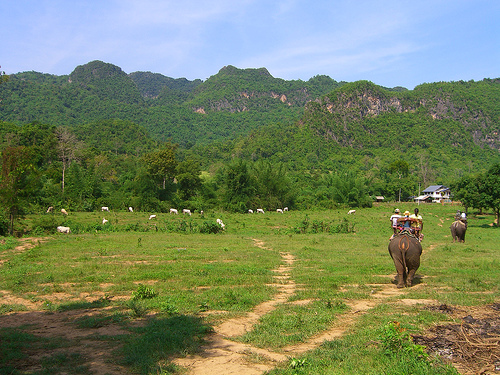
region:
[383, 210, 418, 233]
people riding on top of an elephant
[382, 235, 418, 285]
the elephant the people are riding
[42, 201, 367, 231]
a small herd of wiild animals eating some grass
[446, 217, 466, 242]
another elephant giving people rides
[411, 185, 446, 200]
the house that is in the background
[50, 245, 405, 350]
grass all over the ground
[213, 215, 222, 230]
an animal eating the grass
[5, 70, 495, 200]
tall leafy trees in the background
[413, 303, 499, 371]
a patch of grass on the ground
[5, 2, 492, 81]
the cloudy sky above everything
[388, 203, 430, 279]
people carried by an elephant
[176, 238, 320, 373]
brown paths in the green grass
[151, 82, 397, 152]
a tall green covered mountain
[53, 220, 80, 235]
white horses grazing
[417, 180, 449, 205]
a white house built below the hill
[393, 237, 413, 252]
a clothe covering the elephant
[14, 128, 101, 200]
tall green trees growing at the edge of the hill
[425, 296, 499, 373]
a muddy brown pool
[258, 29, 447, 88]
clear blue sky with little clouds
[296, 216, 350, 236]
green scrubs on the middle of the field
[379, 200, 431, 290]
elephant carry people on his back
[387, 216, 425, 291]
a bench on back of elephant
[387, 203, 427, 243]
three people sit on bench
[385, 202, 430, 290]
people riding an elephant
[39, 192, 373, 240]
sheeps on green field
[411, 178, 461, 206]
a home on the background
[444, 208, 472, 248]
an elephant in motion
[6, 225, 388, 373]
bald spots on green field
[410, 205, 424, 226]
woman combs in a pony tail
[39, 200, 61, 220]
a gray sheep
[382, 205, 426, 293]
people riding on the back on an elephant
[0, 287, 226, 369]
shadow of a tree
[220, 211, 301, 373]
dirt path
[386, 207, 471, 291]
two elephants on a trail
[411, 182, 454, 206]
two story white building with a dark green roof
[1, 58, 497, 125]
rocky mountainous bluffs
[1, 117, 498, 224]
trees on the edge of the field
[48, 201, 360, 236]
white animals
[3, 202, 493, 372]
grassy field bordered by trees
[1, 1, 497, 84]
blue sky with clouds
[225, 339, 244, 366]
part of a groubd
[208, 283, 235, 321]
part of a grass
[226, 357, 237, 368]
part of a floor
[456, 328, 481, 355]
part of a stick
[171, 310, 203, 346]
part of a grass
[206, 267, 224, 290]
part of a grass